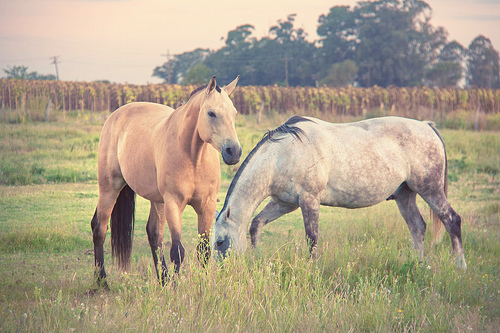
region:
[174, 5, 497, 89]
The trees are leafy.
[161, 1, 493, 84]
The trees are green.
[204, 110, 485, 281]
The horse is grazing.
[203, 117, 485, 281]
The horse is white.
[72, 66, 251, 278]
The horse is brown.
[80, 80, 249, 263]
The horse is standing.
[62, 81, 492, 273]
The horses are next to each other.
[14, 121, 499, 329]
The grass is tall.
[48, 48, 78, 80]
The pole is side ways.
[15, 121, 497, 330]
The grass is green.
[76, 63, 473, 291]
two horses in a field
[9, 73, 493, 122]
corn grows in the background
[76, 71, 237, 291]
the horse on the left is a light brown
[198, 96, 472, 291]
the horse on the right is grey in color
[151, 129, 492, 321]
the horse is grazing in the field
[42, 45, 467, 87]
power lines can be seen in the distance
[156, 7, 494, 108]
trees are in the background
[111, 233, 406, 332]
the grass in front of the horse is long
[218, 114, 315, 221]
the horses mane is black in color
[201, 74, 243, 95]
the horses ears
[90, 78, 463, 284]
two horses in a field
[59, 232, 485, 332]
tall grass in front of the horses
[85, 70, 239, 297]
the tan horse on the left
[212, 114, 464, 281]
the white horse eating grass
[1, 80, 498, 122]
field of corn behind the horses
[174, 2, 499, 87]
tall green trees on the horizon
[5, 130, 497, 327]
a grassy field for the horses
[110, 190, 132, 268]
the tan horse's tail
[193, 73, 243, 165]
the tan horse's head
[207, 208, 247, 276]
the white horse's head in the grass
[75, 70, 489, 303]
Two horses in the meadow.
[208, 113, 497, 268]
One horse is eating.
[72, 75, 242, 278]
The horse on the left is staring out in the distance.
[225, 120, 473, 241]
The horse on the right is grey and black in color.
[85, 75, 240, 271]
Horse on the left is tan and black in color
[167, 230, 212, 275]
The tan horse has black knees.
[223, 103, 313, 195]
The grey horse has a black mane.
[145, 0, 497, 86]
There is a group of trees in the distance.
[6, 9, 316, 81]
The sky has a pink color to it.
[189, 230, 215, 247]
There is tiny flowers in the meadow.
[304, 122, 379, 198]
horse is gray with specks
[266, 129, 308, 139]
horse has black mane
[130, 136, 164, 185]
horse is light tan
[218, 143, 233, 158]
horse has dark nose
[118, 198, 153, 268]
horse has long brown tail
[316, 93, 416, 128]
green and brown foliage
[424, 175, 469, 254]
dark rear flank of horse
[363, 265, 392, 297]
weeds with purple flowers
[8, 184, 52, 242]
green and brown grass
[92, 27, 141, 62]
sky is orange and dusky